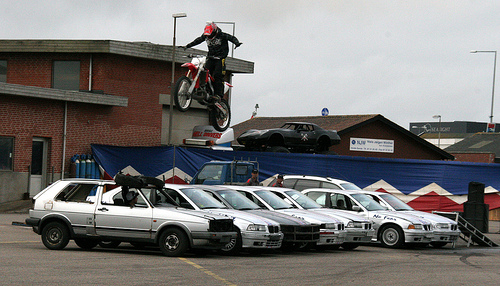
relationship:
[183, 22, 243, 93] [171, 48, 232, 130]
man riding motorcycle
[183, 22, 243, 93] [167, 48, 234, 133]
man riding dirt bike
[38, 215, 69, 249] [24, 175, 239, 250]
tire on car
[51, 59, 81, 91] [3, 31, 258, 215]
window on building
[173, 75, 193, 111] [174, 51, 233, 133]
tire on bike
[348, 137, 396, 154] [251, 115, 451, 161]
sign on building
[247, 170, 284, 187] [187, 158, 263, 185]
people on truck